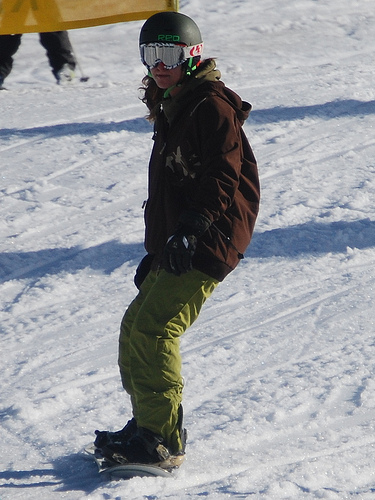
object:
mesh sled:
[90, 418, 193, 485]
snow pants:
[105, 247, 222, 444]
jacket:
[123, 61, 269, 291]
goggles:
[133, 38, 203, 74]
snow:
[9, 6, 374, 485]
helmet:
[132, 6, 212, 56]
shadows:
[256, 79, 374, 275]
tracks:
[203, 280, 360, 477]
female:
[72, 0, 276, 490]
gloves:
[130, 245, 159, 287]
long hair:
[118, 67, 180, 151]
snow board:
[96, 447, 191, 484]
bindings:
[93, 410, 194, 461]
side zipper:
[165, 386, 194, 458]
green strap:
[180, 59, 198, 80]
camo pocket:
[133, 189, 169, 230]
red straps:
[185, 38, 210, 63]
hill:
[9, 265, 374, 496]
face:
[133, 38, 192, 96]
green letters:
[147, 27, 192, 49]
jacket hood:
[202, 59, 267, 132]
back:
[199, 60, 282, 253]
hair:
[130, 68, 170, 129]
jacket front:
[148, 129, 202, 190]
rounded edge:
[92, 454, 169, 479]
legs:
[0, 1, 32, 96]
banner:
[0, 2, 189, 38]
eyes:
[138, 45, 183, 67]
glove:
[167, 232, 206, 277]